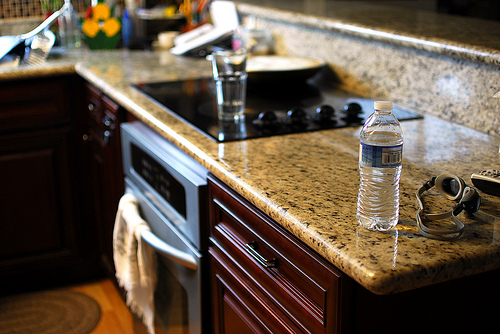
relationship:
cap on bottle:
[373, 98, 394, 113] [354, 102, 403, 230]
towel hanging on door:
[108, 185, 159, 332] [99, 110, 219, 330]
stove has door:
[122, 62, 426, 147] [99, 110, 219, 330]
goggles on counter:
[415, 171, 478, 241] [1, 36, 485, 331]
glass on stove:
[206, 44, 251, 122] [122, 62, 426, 144]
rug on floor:
[17, 292, 98, 333] [87, 282, 132, 330]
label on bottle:
[358, 142, 404, 168] [354, 102, 403, 230]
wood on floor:
[73, 278, 135, 333] [2, 279, 134, 330]